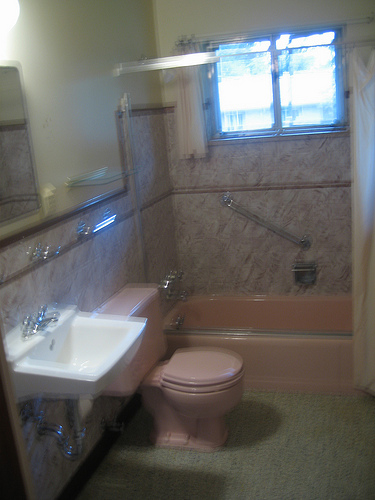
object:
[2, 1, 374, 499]
picture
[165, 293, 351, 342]
bathtub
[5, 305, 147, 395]
bathroom sink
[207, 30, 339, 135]
window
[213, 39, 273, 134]
glass panel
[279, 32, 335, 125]
glass panel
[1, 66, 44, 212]
mirror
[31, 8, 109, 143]
wall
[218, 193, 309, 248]
handle bar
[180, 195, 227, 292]
wall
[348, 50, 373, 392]
shower curtain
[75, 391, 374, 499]
floor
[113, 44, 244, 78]
curtain holder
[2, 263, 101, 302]
wall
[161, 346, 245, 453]
ceramic toilet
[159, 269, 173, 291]
faucet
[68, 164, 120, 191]
glass shelf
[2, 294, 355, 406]
sink and tub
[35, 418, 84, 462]
pipe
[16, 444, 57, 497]
wall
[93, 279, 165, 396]
toilet tank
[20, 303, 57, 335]
faucet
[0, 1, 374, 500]
bathroom